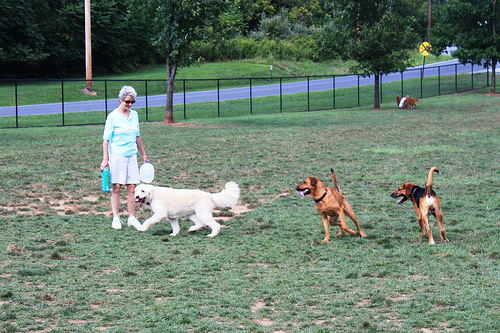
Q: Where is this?
A: This is at the field.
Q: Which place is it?
A: It is a field.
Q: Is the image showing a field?
A: Yes, it is showing a field.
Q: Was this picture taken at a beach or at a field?
A: It was taken at a field.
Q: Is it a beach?
A: No, it is a field.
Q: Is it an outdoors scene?
A: Yes, it is outdoors.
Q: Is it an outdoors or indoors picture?
A: It is outdoors.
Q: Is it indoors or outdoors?
A: It is outdoors.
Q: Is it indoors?
A: No, it is outdoors.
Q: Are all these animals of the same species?
A: Yes, all the animals are dogs.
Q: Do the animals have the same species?
A: Yes, all the animals are dogs.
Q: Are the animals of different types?
A: No, all the animals are dogs.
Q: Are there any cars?
A: No, there are no cars.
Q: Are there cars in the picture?
A: No, there are no cars.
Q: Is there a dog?
A: Yes, there is a dog.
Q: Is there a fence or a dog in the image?
A: Yes, there is a dog.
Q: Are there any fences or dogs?
A: Yes, there is a dog.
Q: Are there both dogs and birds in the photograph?
A: No, there is a dog but no birds.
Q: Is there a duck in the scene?
A: No, there are no ducks.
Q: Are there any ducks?
A: No, there are no ducks.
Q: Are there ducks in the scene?
A: No, there are no ducks.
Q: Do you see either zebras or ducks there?
A: No, there are no ducks or zebras.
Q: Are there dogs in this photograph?
A: Yes, there is a dog.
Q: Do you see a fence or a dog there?
A: Yes, there is a dog.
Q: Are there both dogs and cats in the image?
A: No, there is a dog but no cats.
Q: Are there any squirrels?
A: No, there are no squirrels.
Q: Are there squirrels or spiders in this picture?
A: No, there are no squirrels or spiders.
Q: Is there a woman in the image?
A: Yes, there is a woman.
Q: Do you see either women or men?
A: Yes, there is a woman.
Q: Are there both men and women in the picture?
A: No, there is a woman but no men.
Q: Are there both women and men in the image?
A: No, there is a woman but no men.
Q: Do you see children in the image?
A: No, there are no children.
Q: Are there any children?
A: No, there are no children.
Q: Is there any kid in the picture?
A: No, there are no children.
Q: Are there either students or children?
A: No, there are no children or students.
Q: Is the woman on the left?
A: Yes, the woman is on the left of the image.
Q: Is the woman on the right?
A: No, the woman is on the left of the image.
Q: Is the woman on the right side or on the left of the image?
A: The woman is on the left of the image.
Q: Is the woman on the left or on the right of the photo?
A: The woman is on the left of the image.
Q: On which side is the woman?
A: The woman is on the left of the image.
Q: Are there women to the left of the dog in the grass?
A: Yes, there is a woman to the left of the dog.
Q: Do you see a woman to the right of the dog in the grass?
A: No, the woman is to the left of the dog.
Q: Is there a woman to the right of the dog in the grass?
A: No, the woman is to the left of the dog.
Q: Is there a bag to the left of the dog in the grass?
A: No, there is a woman to the left of the dog.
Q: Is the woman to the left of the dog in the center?
A: Yes, the woman is to the left of the dog.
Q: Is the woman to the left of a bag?
A: No, the woman is to the left of the dog.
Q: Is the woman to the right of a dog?
A: No, the woman is to the left of a dog.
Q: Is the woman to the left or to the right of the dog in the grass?
A: The woman is to the left of the dog.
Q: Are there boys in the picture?
A: No, there are no boys.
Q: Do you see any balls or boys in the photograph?
A: No, there are no boys or balls.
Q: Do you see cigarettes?
A: No, there are no cigarettes.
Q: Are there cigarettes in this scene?
A: No, there are no cigarettes.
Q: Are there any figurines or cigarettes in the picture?
A: No, there are no cigarettes or figurines.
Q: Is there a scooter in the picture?
A: No, there are no scooters.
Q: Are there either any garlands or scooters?
A: No, there are no scooters or garlands.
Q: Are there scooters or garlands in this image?
A: No, there are no scooters or garlands.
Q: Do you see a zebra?
A: No, there are no zebras.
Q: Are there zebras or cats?
A: No, there are no zebras or cats.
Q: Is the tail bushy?
A: Yes, the tail is bushy.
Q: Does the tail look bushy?
A: Yes, the tail is bushy.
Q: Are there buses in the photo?
A: No, there are no buses.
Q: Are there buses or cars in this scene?
A: No, there are no buses or cars.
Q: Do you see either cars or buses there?
A: No, there are no buses or cars.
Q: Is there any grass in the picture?
A: Yes, there is grass.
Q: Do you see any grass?
A: Yes, there is grass.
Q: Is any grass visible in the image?
A: Yes, there is grass.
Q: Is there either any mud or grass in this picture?
A: Yes, there is grass.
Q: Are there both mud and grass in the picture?
A: Yes, there are both grass and mud.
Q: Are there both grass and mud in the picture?
A: Yes, there are both grass and mud.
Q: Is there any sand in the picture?
A: No, there is no sand.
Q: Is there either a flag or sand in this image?
A: No, there are no sand or flags.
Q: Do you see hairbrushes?
A: No, there are no hairbrushes.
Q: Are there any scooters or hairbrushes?
A: No, there are no hairbrushes or scooters.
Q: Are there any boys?
A: No, there are no boys.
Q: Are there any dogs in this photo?
A: Yes, there is a dog.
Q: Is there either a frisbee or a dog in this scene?
A: Yes, there is a dog.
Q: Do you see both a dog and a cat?
A: No, there is a dog but no cats.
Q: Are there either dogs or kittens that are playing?
A: Yes, the dog is playing.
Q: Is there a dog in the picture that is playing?
A: Yes, there is a dog that is playing.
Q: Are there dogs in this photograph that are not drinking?
A: Yes, there is a dog that is playing.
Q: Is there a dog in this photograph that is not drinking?
A: Yes, there is a dog that is playing.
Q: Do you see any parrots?
A: No, there are no parrots.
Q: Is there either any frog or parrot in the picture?
A: No, there are no parrots or frogs.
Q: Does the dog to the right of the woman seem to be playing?
A: Yes, the dog is playing.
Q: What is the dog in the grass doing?
A: The dog is playing.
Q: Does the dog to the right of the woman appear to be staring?
A: No, the dog is playing.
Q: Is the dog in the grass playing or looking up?
A: The dog is playing.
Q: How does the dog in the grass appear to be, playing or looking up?
A: The dog is playing.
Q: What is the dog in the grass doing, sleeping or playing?
A: The dog is playing.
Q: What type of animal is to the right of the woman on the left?
A: The animal is a dog.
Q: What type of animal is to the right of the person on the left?
A: The animal is a dog.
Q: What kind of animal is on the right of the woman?
A: The animal is a dog.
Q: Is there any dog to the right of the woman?
A: Yes, there is a dog to the right of the woman.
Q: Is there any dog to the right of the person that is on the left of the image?
A: Yes, there is a dog to the right of the woman.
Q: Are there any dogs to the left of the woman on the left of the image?
A: No, the dog is to the right of the woman.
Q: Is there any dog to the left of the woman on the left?
A: No, the dog is to the right of the woman.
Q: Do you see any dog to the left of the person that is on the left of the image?
A: No, the dog is to the right of the woman.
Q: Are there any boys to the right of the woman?
A: No, there is a dog to the right of the woman.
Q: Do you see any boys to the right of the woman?
A: No, there is a dog to the right of the woman.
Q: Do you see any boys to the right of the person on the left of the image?
A: No, there is a dog to the right of the woman.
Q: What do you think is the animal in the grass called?
A: The animal is a dog.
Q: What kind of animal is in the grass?
A: The animal is a dog.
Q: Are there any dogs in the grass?
A: Yes, there is a dog in the grass.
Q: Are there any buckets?
A: No, there are no buckets.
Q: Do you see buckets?
A: No, there are no buckets.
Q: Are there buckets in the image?
A: No, there are no buckets.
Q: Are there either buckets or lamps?
A: No, there are no buckets or lamps.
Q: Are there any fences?
A: Yes, there is a fence.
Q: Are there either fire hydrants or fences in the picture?
A: Yes, there is a fence.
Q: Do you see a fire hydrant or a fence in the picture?
A: Yes, there is a fence.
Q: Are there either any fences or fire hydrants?
A: Yes, there is a fence.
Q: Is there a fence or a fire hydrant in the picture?
A: Yes, there is a fence.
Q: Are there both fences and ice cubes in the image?
A: No, there is a fence but no ice cubes.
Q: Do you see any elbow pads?
A: No, there are no elbow pads.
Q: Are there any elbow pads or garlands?
A: No, there are no elbow pads or garlands.